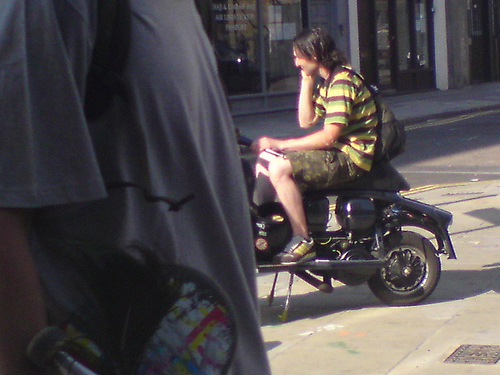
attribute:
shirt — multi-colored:
[302, 64, 389, 175]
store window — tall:
[414, 0, 435, 72]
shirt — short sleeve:
[307, 67, 377, 169]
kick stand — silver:
[234, 243, 337, 335]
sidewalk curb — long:
[397, 104, 498, 124]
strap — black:
[52, 30, 157, 135]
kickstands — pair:
[258, 266, 326, 328]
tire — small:
[371, 224, 447, 310]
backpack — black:
[318, 64, 411, 171]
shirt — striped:
[313, 70, 382, 170]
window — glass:
[211, 4, 253, 39]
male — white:
[253, 32, 383, 263]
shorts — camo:
[275, 147, 372, 194]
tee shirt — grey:
[5, 3, 268, 373]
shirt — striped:
[307, 69, 390, 165]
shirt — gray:
[8, 21, 324, 342]